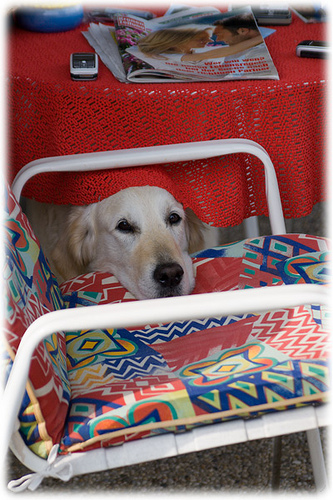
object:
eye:
[115, 217, 135, 234]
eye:
[166, 211, 180, 225]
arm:
[12, 137, 288, 235]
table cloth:
[10, 2, 332, 227]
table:
[6, 7, 331, 244]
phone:
[69, 52, 98, 81]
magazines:
[81, 5, 279, 84]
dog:
[23, 184, 215, 301]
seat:
[6, 191, 327, 461]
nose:
[153, 261, 184, 288]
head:
[68, 184, 209, 301]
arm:
[4, 278, 332, 454]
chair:
[4, 137, 332, 490]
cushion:
[5, 189, 330, 462]